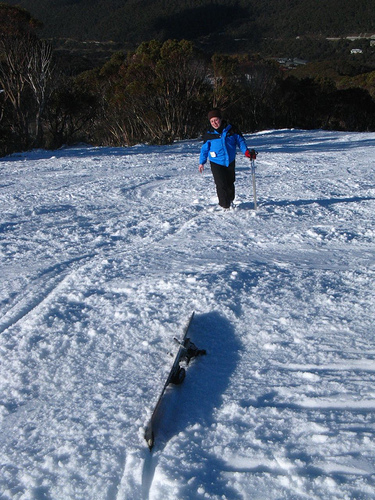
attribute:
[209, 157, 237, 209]
pants — black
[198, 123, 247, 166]
coat — black, blue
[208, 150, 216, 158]
paper — white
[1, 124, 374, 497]
slope — snowy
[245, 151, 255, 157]
gloves — red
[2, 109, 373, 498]
ski slope — snowy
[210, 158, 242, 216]
pants — black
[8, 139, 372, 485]
ground — white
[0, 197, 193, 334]
tracks — long, narrow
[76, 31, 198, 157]
tree — large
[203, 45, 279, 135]
tree — large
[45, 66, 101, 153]
tree — large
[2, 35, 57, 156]
tree — large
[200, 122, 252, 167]
coat — blue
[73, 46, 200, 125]
tree — large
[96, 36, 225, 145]
tree — large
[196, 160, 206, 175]
hand — gloveless